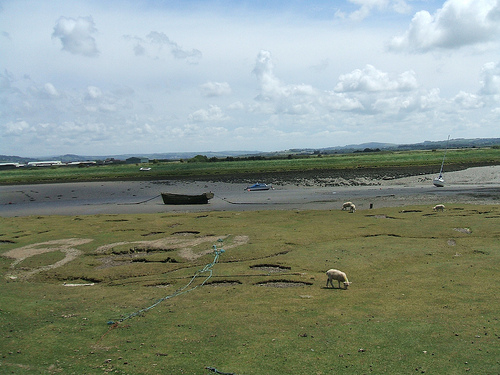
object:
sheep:
[325, 268, 352, 290]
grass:
[220, 295, 498, 374]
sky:
[3, 1, 500, 146]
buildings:
[27, 160, 62, 166]